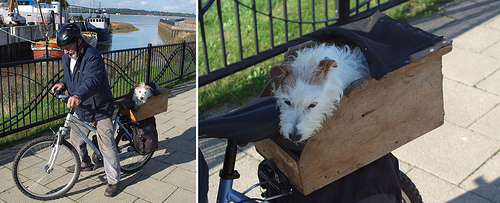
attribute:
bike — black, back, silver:
[11, 81, 169, 201]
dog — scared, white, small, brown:
[130, 82, 155, 112]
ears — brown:
[132, 83, 154, 90]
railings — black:
[1, 42, 196, 136]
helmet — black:
[56, 21, 83, 50]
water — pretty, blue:
[70, 9, 183, 55]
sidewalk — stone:
[2, 78, 197, 202]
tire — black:
[116, 121, 159, 175]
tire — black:
[11, 134, 82, 201]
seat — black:
[113, 99, 136, 110]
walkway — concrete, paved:
[200, 2, 500, 202]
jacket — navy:
[60, 42, 116, 122]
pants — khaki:
[69, 107, 121, 185]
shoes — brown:
[66, 163, 120, 197]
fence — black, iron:
[198, 2, 403, 88]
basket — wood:
[256, 13, 454, 195]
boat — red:
[31, 31, 100, 62]